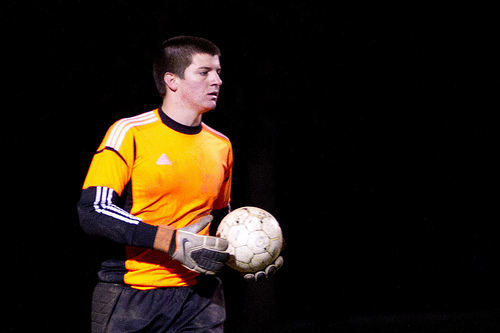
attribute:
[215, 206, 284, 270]
ball — soccer, white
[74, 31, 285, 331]
goalie — man, player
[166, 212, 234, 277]
glove — padded, thick, heavy-duty, gray, black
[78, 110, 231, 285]
shirt — yellow, black, orange, gold, white, jersey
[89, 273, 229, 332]
shorts — dusty, black, wrinkled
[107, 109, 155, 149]
stripes — white, triple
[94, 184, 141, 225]
stripes — white, triple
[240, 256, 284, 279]
glove — heavy-duty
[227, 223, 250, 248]
hexagon — shape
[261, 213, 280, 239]
hexagon — shape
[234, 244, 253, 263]
hexagon — shape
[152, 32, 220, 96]
hair — short, black, brown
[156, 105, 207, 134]
trim — black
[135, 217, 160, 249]
cuff — black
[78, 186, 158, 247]
sleeve — blue